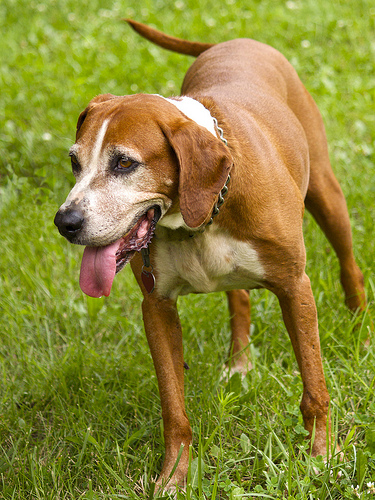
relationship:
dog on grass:
[48, 14, 367, 498] [4, 8, 373, 494]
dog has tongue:
[48, 14, 367, 498] [77, 247, 119, 300]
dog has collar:
[48, 14, 367, 498] [132, 97, 235, 294]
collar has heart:
[132, 97, 235, 294] [139, 269, 160, 296]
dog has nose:
[48, 14, 367, 498] [53, 208, 84, 240]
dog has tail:
[48, 14, 367, 498] [119, 14, 214, 62]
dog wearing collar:
[48, 14, 367, 498] [132, 97, 235, 294]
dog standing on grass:
[48, 14, 367, 498] [4, 8, 373, 494]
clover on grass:
[217, 477, 236, 493] [4, 8, 373, 494]